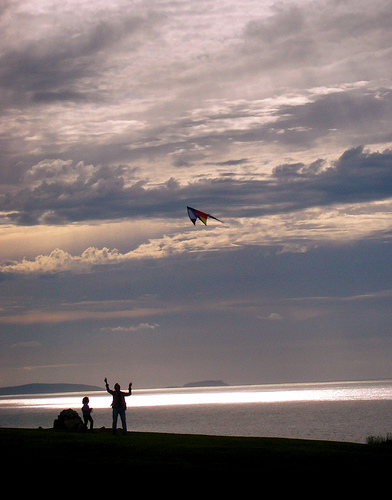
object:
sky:
[1, 2, 391, 385]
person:
[103, 376, 134, 435]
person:
[81, 394, 94, 430]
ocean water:
[1, 379, 391, 444]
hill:
[0, 376, 109, 394]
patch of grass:
[365, 434, 391, 445]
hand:
[103, 378, 108, 384]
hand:
[127, 382, 134, 388]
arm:
[105, 379, 115, 395]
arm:
[122, 382, 135, 396]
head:
[114, 383, 121, 391]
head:
[81, 396, 90, 405]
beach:
[0, 426, 391, 499]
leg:
[119, 410, 126, 428]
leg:
[112, 411, 118, 430]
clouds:
[2, 2, 392, 385]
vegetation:
[51, 406, 87, 429]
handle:
[104, 376, 108, 382]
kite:
[186, 206, 223, 227]